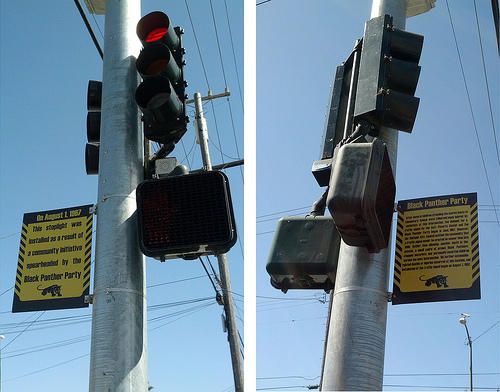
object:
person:
[248, 137, 418, 201]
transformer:
[186, 87, 231, 104]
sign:
[10, 204, 92, 314]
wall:
[416, 112, 459, 163]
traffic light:
[133, 10, 189, 144]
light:
[459, 313, 469, 325]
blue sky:
[1, 1, 492, 390]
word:
[45, 211, 64, 219]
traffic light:
[352, 14, 422, 133]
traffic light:
[84, 80, 102, 176]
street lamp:
[458, 310, 475, 390]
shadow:
[98, 68, 137, 384]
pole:
[92, 0, 149, 391]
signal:
[135, 170, 238, 261]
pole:
[320, 2, 409, 392]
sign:
[391, 191, 481, 305]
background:
[390, 191, 481, 307]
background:
[9, 203, 95, 313]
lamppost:
[458, 317, 472, 389]